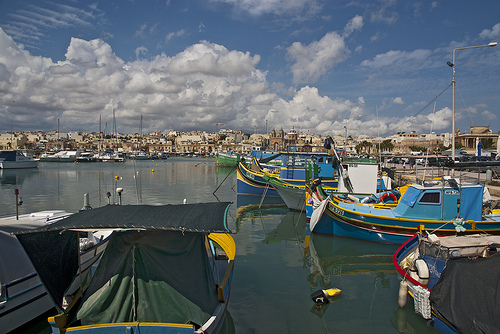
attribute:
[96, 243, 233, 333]
tarp — green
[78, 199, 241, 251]
tarp — black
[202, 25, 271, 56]
sky — cloudy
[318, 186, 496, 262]
boat — blue, blue yellow, red, striped, red blue, yellow, red yellow, green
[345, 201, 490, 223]
stripe — yellow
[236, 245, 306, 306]
water — calm, green, clear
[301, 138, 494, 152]
buildings — in background, distant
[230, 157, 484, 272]
boats — at marina, in marina, colorful, in large marina, blue, bright, plentiful, tied up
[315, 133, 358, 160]
umbrella — black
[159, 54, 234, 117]
clouds — white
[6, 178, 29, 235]
light — metal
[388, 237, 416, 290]
trim — red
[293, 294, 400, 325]
object — yellow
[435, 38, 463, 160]
light — tall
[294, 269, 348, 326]
buoy — floating